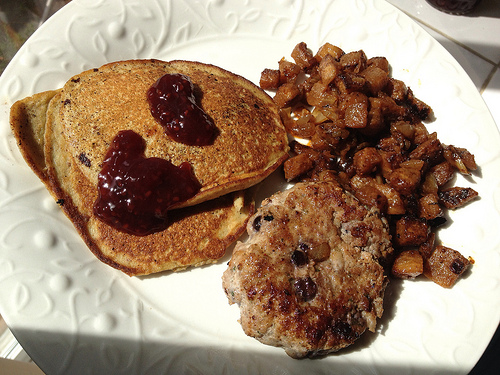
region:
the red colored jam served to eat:
[96, 121, 191, 239]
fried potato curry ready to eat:
[295, 42, 402, 149]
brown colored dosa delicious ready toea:
[58, 61, 223, 273]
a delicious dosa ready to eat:
[256, 176, 397, 348]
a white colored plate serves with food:
[15, 26, 365, 371]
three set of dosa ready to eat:
[16, 71, 223, 269]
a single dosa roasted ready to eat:
[254, 186, 409, 349]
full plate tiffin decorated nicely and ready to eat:
[36, 35, 468, 350]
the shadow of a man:
[465, 34, 497, 93]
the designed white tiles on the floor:
[459, 23, 498, 83]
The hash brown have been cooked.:
[265, 43, 472, 278]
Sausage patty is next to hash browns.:
[222, 181, 394, 362]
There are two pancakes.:
[3, 55, 294, 285]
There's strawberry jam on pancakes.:
[90, 60, 219, 235]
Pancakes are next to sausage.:
[6, 47, 288, 279]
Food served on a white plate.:
[1, 2, 497, 374]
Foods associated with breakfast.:
[11, 45, 480, 361]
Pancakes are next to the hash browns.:
[6, 51, 300, 284]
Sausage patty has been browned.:
[219, 179, 400, 368]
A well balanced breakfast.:
[9, 36, 496, 369]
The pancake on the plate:
[10, 52, 267, 279]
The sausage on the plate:
[222, 171, 395, 358]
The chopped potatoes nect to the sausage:
[259, 33, 480, 294]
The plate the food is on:
[4, 1, 494, 373]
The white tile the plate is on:
[389, 0, 499, 136]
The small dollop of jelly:
[141, 70, 220, 148]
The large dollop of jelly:
[92, 128, 201, 241]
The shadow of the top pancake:
[170, 190, 266, 226]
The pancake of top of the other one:
[61, 57, 290, 207]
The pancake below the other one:
[9, 88, 256, 278]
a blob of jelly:
[136, 63, 246, 182]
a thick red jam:
[78, 113, 208, 246]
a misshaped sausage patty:
[209, 146, 404, 360]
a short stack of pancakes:
[14, 38, 265, 295]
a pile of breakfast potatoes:
[280, 40, 437, 184]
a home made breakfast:
[14, 29, 492, 347]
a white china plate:
[6, 7, 488, 364]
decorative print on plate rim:
[13, 268, 176, 372]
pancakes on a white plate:
[16, 26, 320, 333]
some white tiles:
[407, 4, 498, 91]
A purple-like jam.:
[103, 132, 198, 231]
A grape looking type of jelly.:
[147, 75, 217, 146]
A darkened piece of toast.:
[41, 76, 281, 176]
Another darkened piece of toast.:
[15, 90, 245, 270]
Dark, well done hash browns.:
[257, 40, 477, 286]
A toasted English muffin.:
[220, 169, 392, 361]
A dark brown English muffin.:
[225, 181, 392, 358]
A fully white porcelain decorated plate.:
[0, 0, 496, 371]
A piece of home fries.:
[440, 185, 475, 200]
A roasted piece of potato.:
[393, 251, 424, 281]